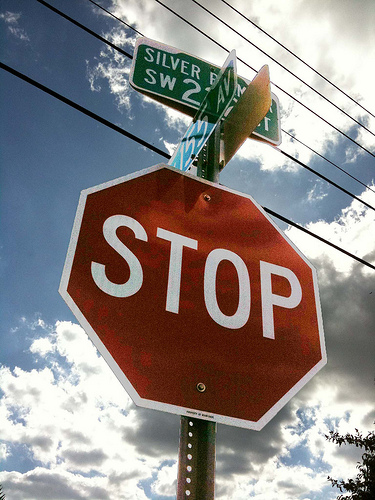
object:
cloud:
[0, 0, 375, 499]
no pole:
[20, 151, 48, 168]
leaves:
[362, 455, 371, 468]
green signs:
[129, 37, 282, 145]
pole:
[176, 107, 222, 499]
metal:
[173, 413, 219, 499]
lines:
[0, 0, 375, 274]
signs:
[59, 169, 329, 437]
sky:
[0, 1, 375, 500]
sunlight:
[24, 334, 91, 453]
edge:
[58, 289, 139, 404]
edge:
[312, 267, 326, 362]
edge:
[82, 162, 167, 197]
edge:
[250, 193, 315, 273]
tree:
[325, 422, 375, 499]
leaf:
[328, 425, 344, 445]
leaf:
[331, 478, 345, 490]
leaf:
[345, 424, 360, 447]